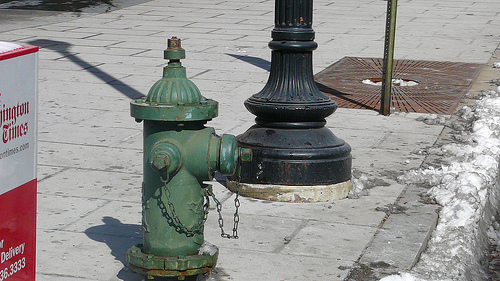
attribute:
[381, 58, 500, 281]
snow — white, dirty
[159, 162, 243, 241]
chain — silver, hanging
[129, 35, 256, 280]
hydrant — green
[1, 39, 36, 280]
paper machine — coin operated, white, red, washington times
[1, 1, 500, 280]
sidewalk — cement, chipping, wet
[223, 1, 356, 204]
pole — black, green, decorative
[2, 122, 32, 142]
time — red, white, in red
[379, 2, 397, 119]
pole — green, metal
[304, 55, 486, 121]
cover — square, brown, mahole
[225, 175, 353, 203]
concrete — round